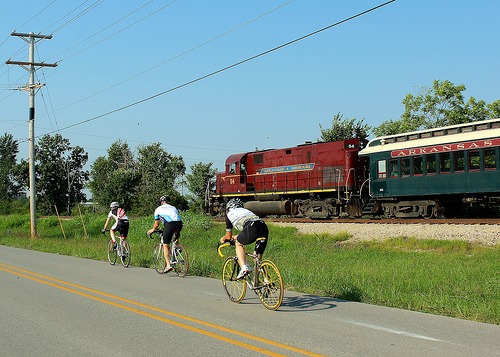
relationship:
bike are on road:
[146, 227, 190, 278] [0, 243, 499, 355]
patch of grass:
[430, 252, 489, 301] [0, 215, 498, 324]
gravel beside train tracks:
[264, 220, 500, 250] [2, 211, 498, 232]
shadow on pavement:
[240, 292, 351, 313] [0, 243, 499, 355]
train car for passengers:
[356, 117, 500, 194] [390, 163, 409, 176]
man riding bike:
[218, 196, 273, 284] [213, 234, 287, 312]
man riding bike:
[151, 192, 182, 272] [149, 227, 193, 278]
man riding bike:
[99, 197, 135, 252] [100, 225, 136, 270]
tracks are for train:
[2, 211, 498, 232] [201, 118, 497, 217]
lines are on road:
[0, 255, 329, 356] [0, 243, 499, 355]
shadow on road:
[240, 292, 351, 313] [0, 243, 499, 355]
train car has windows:
[356, 117, 500, 194] [385, 147, 495, 178]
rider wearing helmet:
[218, 196, 273, 284] [225, 195, 248, 214]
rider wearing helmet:
[151, 192, 182, 272] [157, 193, 171, 203]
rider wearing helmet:
[99, 197, 135, 252] [109, 199, 123, 213]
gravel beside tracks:
[264, 220, 500, 250] [2, 211, 498, 232]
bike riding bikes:
[146, 227, 190, 278] [99, 227, 283, 315]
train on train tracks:
[201, 118, 497, 217] [2, 211, 498, 232]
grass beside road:
[0, 215, 498, 324] [0, 243, 499, 355]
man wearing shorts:
[218, 196, 273, 284] [237, 219, 269, 253]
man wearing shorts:
[151, 192, 182, 272] [159, 219, 182, 244]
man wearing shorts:
[99, 197, 135, 252] [111, 217, 133, 238]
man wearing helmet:
[218, 196, 273, 284] [225, 195, 248, 214]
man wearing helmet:
[151, 192, 182, 272] [157, 193, 171, 203]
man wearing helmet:
[99, 197, 135, 252] [109, 199, 123, 213]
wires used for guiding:
[31, 43, 93, 244] [57, 220, 100, 249]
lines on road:
[0, 255, 329, 356] [0, 243, 499, 355]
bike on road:
[146, 227, 190, 278] [0, 243, 499, 355]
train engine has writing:
[213, 136, 365, 197] [262, 164, 313, 173]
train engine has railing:
[213, 136, 365, 197] [253, 168, 358, 190]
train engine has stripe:
[213, 136, 365, 197] [211, 187, 339, 199]